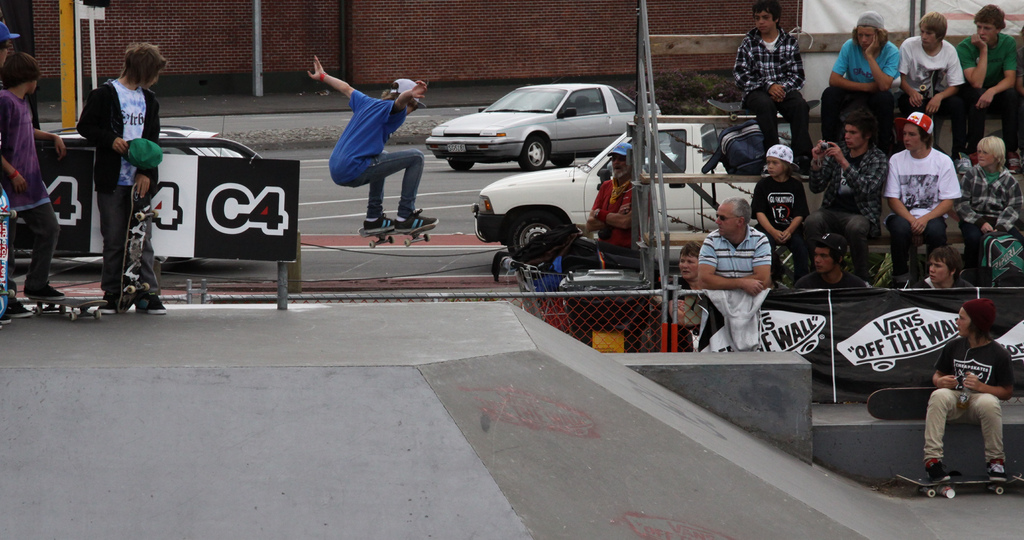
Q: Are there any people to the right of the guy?
A: Yes, there is a person to the right of the guy.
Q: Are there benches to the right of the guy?
A: No, there is a person to the right of the guy.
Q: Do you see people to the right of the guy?
A: Yes, there is a person to the right of the guy.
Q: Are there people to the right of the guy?
A: Yes, there is a person to the right of the guy.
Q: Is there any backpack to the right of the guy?
A: No, there is a person to the right of the guy.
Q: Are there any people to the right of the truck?
A: Yes, there is a person to the right of the truck.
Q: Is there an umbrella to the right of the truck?
A: No, there is a person to the right of the truck.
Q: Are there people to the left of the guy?
A: Yes, there is a person to the left of the guy.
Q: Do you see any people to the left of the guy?
A: Yes, there is a person to the left of the guy.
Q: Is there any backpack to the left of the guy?
A: No, there is a person to the left of the guy.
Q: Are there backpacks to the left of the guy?
A: No, there is a person to the left of the guy.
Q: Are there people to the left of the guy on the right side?
A: Yes, there is a person to the left of the guy.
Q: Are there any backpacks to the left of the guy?
A: No, there is a person to the left of the guy.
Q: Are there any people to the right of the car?
A: Yes, there is a person to the right of the car.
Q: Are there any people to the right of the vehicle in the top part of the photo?
A: Yes, there is a person to the right of the car.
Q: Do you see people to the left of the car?
A: No, the person is to the right of the car.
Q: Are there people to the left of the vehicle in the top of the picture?
A: No, the person is to the right of the car.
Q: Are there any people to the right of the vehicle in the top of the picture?
A: Yes, there is a person to the right of the car.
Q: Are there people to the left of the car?
A: No, the person is to the right of the car.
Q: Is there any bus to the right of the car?
A: No, there is a person to the right of the car.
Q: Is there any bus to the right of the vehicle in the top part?
A: No, there is a person to the right of the car.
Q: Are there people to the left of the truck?
A: No, the person is to the right of the truck.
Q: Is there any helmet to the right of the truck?
A: No, there is a person to the right of the truck.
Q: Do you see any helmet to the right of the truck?
A: No, there is a person to the right of the truck.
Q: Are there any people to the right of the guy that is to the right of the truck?
A: Yes, there is a person to the right of the guy.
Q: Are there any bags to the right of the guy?
A: No, there is a person to the right of the guy.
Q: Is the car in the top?
A: Yes, the car is in the top of the image.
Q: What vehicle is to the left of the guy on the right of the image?
A: The vehicle is a car.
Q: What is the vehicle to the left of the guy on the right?
A: The vehicle is a car.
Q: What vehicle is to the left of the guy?
A: The vehicle is a car.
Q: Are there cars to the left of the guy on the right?
A: Yes, there is a car to the left of the guy.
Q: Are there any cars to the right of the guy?
A: No, the car is to the left of the guy.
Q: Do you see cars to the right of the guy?
A: No, the car is to the left of the guy.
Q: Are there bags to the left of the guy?
A: No, there is a car to the left of the guy.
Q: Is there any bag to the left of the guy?
A: No, there is a car to the left of the guy.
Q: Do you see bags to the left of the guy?
A: No, there is a car to the left of the guy.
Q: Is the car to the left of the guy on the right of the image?
A: Yes, the car is to the left of the guy.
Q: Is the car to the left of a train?
A: No, the car is to the left of the guy.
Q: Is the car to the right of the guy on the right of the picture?
A: No, the car is to the left of the guy.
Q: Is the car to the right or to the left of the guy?
A: The car is to the left of the guy.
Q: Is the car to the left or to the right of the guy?
A: The car is to the left of the guy.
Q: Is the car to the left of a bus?
A: No, the car is to the left of a person.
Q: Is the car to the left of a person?
A: Yes, the car is to the left of a person.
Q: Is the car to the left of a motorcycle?
A: No, the car is to the left of a person.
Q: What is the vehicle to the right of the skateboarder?
A: The vehicle is a car.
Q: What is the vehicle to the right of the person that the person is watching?
A: The vehicle is a car.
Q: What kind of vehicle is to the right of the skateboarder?
A: The vehicle is a car.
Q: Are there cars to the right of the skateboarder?
A: Yes, there is a car to the right of the skateboarder.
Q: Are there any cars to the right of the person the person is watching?
A: Yes, there is a car to the right of the skateboarder.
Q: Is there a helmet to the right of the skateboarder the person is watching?
A: No, there is a car to the right of the skateboarder.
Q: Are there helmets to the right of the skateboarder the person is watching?
A: No, there is a car to the right of the skateboarder.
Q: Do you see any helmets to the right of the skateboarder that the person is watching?
A: No, there is a car to the right of the skateboarder.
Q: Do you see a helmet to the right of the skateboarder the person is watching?
A: No, there is a car to the right of the skateboarder.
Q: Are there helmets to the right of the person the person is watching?
A: No, there is a car to the right of the skateboarder.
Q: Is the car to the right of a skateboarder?
A: Yes, the car is to the right of a skateboarder.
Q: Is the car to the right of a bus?
A: No, the car is to the right of a skateboarder.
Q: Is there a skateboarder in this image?
A: Yes, there is a skateboarder.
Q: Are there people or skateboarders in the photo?
A: Yes, there is a skateboarder.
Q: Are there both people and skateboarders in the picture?
A: Yes, there are both a skateboarder and people.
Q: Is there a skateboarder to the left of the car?
A: Yes, there is a skateboarder to the left of the car.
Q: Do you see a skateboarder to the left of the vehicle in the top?
A: Yes, there is a skateboarder to the left of the car.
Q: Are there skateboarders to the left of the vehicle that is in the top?
A: Yes, there is a skateboarder to the left of the car.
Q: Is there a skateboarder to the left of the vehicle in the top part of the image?
A: Yes, there is a skateboarder to the left of the car.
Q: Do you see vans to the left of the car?
A: No, there is a skateboarder to the left of the car.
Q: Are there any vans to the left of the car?
A: No, there is a skateboarder to the left of the car.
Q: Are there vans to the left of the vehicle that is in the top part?
A: No, there is a skateboarder to the left of the car.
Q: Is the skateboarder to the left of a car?
A: Yes, the skateboarder is to the left of a car.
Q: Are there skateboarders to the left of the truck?
A: Yes, there is a skateboarder to the left of the truck.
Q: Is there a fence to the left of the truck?
A: No, there is a skateboarder to the left of the truck.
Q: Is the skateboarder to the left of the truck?
A: Yes, the skateboarder is to the left of the truck.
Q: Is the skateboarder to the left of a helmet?
A: No, the skateboarder is to the left of the truck.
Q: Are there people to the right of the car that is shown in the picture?
A: Yes, there is a person to the right of the car.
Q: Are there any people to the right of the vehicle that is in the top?
A: Yes, there is a person to the right of the car.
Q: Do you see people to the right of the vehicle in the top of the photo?
A: Yes, there is a person to the right of the car.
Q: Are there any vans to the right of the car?
A: No, there is a person to the right of the car.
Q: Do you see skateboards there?
A: Yes, there is a skateboard.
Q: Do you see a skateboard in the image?
A: Yes, there is a skateboard.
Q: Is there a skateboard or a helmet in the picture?
A: Yes, there is a skateboard.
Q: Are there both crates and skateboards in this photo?
A: No, there is a skateboard but no crates.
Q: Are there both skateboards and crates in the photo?
A: No, there is a skateboard but no crates.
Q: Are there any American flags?
A: No, there are no American flags.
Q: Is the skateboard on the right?
A: Yes, the skateboard is on the right of the image.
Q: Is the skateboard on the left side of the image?
A: No, the skateboard is on the right of the image.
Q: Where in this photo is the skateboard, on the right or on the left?
A: The skateboard is on the right of the image.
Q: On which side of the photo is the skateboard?
A: The skateboard is on the right of the image.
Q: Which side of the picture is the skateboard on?
A: The skateboard is on the right of the image.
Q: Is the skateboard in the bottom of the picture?
A: Yes, the skateboard is in the bottom of the image.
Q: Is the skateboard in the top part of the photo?
A: No, the skateboard is in the bottom of the image.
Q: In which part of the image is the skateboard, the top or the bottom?
A: The skateboard is in the bottom of the image.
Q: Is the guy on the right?
A: Yes, the guy is on the right of the image.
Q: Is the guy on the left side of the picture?
A: No, the guy is on the right of the image.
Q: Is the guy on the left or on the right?
A: The guy is on the right of the image.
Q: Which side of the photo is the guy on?
A: The guy is on the right of the image.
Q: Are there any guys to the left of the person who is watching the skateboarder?
A: Yes, there is a guy to the left of the person.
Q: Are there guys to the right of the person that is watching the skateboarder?
A: No, the guy is to the left of the person.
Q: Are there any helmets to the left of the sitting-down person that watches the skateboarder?
A: No, there is a guy to the left of the person.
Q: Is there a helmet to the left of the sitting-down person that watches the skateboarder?
A: No, there is a guy to the left of the person.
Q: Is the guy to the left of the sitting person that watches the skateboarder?
A: Yes, the guy is to the left of the person.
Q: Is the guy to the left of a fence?
A: No, the guy is to the left of the person.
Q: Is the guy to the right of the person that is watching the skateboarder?
A: No, the guy is to the left of the person.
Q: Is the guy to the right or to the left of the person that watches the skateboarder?
A: The guy is to the left of the person.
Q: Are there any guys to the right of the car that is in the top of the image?
A: Yes, there is a guy to the right of the car.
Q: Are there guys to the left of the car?
A: No, the guy is to the right of the car.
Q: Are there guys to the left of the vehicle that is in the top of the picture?
A: No, the guy is to the right of the car.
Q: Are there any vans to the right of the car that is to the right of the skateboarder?
A: No, there is a guy to the right of the car.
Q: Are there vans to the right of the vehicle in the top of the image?
A: No, there is a guy to the right of the car.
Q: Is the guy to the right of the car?
A: Yes, the guy is to the right of the car.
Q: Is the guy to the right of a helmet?
A: No, the guy is to the right of the car.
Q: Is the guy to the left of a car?
A: No, the guy is to the right of a car.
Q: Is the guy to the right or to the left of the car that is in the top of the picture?
A: The guy is to the right of the car.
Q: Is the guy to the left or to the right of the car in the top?
A: The guy is to the right of the car.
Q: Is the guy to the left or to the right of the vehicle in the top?
A: The guy is to the right of the car.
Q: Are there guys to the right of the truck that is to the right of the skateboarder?
A: Yes, there is a guy to the right of the truck.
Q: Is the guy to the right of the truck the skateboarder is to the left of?
A: Yes, the guy is to the right of the truck.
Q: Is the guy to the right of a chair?
A: No, the guy is to the right of the truck.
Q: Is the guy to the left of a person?
A: Yes, the guy is to the left of a person.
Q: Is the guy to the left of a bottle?
A: No, the guy is to the left of a person.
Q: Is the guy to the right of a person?
A: No, the guy is to the left of a person.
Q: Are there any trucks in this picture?
A: Yes, there is a truck.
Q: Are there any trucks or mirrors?
A: Yes, there is a truck.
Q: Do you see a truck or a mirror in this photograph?
A: Yes, there is a truck.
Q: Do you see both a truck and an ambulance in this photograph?
A: No, there is a truck but no ambulances.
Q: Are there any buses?
A: No, there are no buses.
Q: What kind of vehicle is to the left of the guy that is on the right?
A: The vehicle is a truck.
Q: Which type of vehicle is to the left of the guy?
A: The vehicle is a truck.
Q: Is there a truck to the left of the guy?
A: Yes, there is a truck to the left of the guy.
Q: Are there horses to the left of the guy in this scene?
A: No, there is a truck to the left of the guy.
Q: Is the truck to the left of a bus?
A: No, the truck is to the left of the guy.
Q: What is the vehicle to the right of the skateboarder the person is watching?
A: The vehicle is a truck.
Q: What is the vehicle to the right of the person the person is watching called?
A: The vehicle is a truck.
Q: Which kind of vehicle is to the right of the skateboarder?
A: The vehicle is a truck.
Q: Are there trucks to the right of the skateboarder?
A: Yes, there is a truck to the right of the skateboarder.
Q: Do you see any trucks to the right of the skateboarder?
A: Yes, there is a truck to the right of the skateboarder.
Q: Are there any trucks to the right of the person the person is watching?
A: Yes, there is a truck to the right of the skateboarder.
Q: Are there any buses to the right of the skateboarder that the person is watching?
A: No, there is a truck to the right of the skateboarder.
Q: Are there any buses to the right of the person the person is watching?
A: No, there is a truck to the right of the skateboarder.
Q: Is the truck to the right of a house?
A: No, the truck is to the right of the skateboarder.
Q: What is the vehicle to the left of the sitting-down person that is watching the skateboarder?
A: The vehicle is a truck.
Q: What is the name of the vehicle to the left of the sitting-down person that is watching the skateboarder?
A: The vehicle is a truck.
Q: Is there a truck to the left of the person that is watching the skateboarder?
A: Yes, there is a truck to the left of the person.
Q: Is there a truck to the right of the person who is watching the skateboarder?
A: No, the truck is to the left of the person.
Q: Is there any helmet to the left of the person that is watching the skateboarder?
A: No, there is a truck to the left of the person.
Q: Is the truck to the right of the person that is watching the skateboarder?
A: No, the truck is to the left of the person.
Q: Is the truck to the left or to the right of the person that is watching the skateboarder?
A: The truck is to the left of the person.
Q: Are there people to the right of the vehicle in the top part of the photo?
A: Yes, there are people to the right of the car.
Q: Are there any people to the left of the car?
A: No, the people are to the right of the car.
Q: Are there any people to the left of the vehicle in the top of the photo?
A: No, the people are to the right of the car.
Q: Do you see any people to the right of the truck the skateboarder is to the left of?
A: Yes, there are people to the right of the truck.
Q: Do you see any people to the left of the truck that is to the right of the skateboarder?
A: No, the people are to the right of the truck.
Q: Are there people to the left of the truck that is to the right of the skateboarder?
A: No, the people are to the right of the truck.